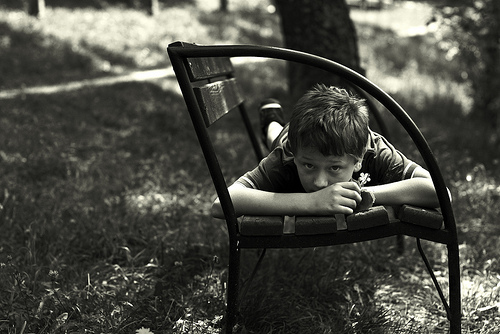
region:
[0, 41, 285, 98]
Pathway behind park bench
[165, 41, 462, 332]
Park bench in partial shade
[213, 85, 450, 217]
Boy lying on park bench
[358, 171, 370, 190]
Small wild flower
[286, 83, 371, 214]
Boy holding small wild flower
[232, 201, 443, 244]
Curved wooden seat on park bench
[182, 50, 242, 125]
Wooden back on park bench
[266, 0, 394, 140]
Tree behind the park bench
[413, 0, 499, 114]
A tree and tall weeds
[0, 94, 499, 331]
Weeds under and near the park bench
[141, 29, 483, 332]
a boy on a bench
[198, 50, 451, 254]
boy laying down on a bench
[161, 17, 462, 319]
a bench by a tree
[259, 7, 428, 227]
a dark trunk of tree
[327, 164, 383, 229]
a small flower in his hand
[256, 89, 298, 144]
a black shoe on his foot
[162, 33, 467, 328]
black metal bar of bench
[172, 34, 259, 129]
two back slats of bench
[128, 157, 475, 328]
sunlight shines on the ground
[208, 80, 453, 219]
Boy lying on a bench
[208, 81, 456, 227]
Boy holding a small flower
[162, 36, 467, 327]
A bench under a tree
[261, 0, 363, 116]
Part of a tree trunk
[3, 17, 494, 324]
Grass covered hill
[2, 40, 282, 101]
A sidewalk on a hill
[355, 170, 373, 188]
A small flower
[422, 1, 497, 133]
A bush in the background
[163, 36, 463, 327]
A metal bench with wooden seat and back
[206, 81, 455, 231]
A young boy lying on his stomach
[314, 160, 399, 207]
a small flower in his hand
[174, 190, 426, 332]
shadow under the bench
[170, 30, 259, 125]
two slats for back of bench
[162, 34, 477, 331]
black metal arm of bench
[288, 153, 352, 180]
two eyes of the boy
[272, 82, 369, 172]
short brown hair on boy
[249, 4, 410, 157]
a tree behind the bench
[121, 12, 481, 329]
a bench in the grass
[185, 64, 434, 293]
a boy on a bench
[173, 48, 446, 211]
boy laying on a bench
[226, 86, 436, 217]
boy lays on his stomach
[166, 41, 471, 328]
a wood slatted park bench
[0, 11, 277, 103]
a walkway through a park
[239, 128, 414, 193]
a dark shirt with white stripe around the sleeve cuff and collar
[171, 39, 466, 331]
high rounded bench arms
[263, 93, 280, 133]
dark sneaker with white sole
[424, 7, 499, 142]
a shrub to the right in the picture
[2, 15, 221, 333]
shady area cast by a large tree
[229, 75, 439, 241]
The boy on the bench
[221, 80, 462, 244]
A boy on the bench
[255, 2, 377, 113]
The brown tree stump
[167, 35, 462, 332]
child laying on a bench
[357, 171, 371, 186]
five petal flower